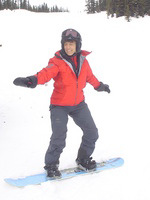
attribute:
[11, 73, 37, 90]
glove — black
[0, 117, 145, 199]
snow — smooth, white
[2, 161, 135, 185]
snowboard — thin, blue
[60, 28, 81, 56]
helmet — black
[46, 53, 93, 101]
pants — orange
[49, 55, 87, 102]
jacket — red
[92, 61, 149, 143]
snow — white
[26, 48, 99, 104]
jacket — red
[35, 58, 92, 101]
jacket — red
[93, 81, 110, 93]
glove — black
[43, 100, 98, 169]
pants — blue